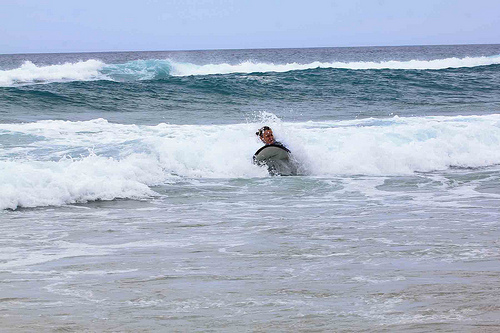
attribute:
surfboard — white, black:
[251, 141, 295, 177]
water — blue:
[0, 45, 499, 331]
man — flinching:
[254, 122, 286, 150]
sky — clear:
[2, 0, 499, 54]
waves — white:
[1, 53, 498, 210]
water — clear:
[0, 164, 499, 329]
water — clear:
[345, 284, 484, 333]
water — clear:
[278, 240, 387, 327]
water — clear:
[145, 250, 226, 305]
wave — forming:
[196, 145, 246, 201]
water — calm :
[320, 186, 496, 324]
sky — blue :
[2, 6, 498, 38]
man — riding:
[243, 122, 277, 152]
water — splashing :
[57, 120, 276, 240]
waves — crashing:
[28, 40, 469, 130]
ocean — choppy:
[18, 51, 439, 152]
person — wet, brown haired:
[245, 126, 308, 185]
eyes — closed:
[246, 120, 291, 152]